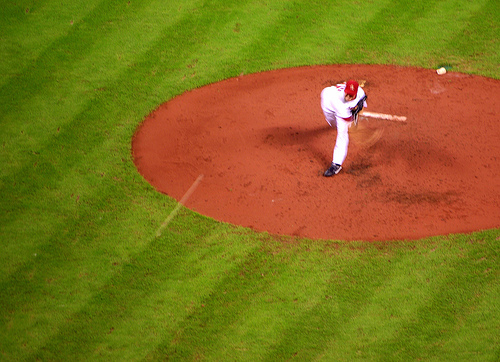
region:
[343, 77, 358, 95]
red color hat of the player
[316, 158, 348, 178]
a person wearing black color shoe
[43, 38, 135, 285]
green grass in the ground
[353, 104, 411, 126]
a bat on the person hand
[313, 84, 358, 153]
a man wearing white color dress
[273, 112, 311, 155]
shadow of the person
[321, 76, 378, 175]
a player holding bat to hit the ball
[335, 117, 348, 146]
knee of the person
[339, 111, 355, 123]
elbow of the person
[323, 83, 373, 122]
white color shirt of the person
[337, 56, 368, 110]
head of a person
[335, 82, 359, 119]
arm of a person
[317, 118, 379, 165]
leg of a person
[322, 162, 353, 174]
feet of a person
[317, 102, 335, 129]
leg of a person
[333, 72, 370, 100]
person wearing a hat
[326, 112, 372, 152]
a leg of a person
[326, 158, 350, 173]
a feet of a person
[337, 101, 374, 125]
an arm of a person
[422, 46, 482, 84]
ball in mid air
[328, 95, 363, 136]
arm of a person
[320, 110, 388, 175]
a leg of a person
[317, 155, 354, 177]
a feet of a person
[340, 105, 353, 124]
an arm of a person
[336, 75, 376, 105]
a head of a person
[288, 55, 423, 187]
person wearing a hat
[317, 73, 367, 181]
baseball player wearing white uniform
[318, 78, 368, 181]
baseball player wearing red cap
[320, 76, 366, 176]
baseball pitcher pitching ball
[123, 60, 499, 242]
pitcher's mound on field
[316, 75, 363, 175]
baseball pitcher on mound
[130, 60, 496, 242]
pitcher's mound on baseball field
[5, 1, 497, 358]
green baseball field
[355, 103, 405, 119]
markings on pitcher's mound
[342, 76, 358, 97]
red baseball cap worn by pitcher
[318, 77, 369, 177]
pitcher bent over after pitching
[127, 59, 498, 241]
Pitcher standing on the pitcher's mound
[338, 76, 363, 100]
A red colored hat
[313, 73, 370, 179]
Baseball player wearing a white uniform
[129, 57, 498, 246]
The pitcher's mound is round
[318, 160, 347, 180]
The sneaker is black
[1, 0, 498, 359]
Green grass on the field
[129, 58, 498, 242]
Brown dirt on the pitcher's mound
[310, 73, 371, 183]
The pitcher has just thrown the ball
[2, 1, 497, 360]
A baseball game is taking place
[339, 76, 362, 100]
White symbol on red hat